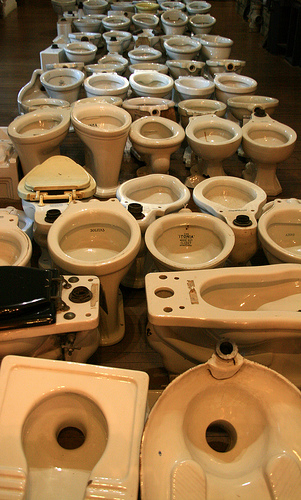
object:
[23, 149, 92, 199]
toilet seat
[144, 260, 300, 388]
toilet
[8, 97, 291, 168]
row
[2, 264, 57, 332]
toilet seat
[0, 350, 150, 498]
toilet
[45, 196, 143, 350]
fixture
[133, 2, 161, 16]
toilet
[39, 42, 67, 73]
tank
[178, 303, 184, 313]
hole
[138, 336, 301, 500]
sink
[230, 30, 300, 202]
floor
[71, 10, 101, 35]
toilets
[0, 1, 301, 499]
background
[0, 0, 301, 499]
room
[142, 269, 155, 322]
edge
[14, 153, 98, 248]
toilet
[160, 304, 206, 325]
valve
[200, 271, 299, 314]
no lid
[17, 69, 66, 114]
water basin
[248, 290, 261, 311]
inside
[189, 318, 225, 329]
part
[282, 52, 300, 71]
edge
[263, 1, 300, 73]
shade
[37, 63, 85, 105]
toilet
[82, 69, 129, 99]
toilet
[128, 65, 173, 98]
toilet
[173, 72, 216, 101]
toilet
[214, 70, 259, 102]
toilet